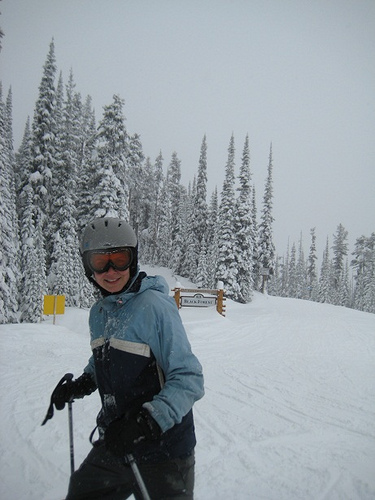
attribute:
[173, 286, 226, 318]
sign — in the background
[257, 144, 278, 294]
pine tree — snow covered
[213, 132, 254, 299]
pine tree — snow covered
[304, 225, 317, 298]
pine tree — snow covered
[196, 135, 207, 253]
pine tree — snow covered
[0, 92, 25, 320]
pine tree — snow covered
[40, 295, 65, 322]
sign — yellow 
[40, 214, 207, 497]
female skier — in blue, in black, dressed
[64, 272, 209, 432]
jacket — blue , black 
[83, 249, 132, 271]
goggles — orange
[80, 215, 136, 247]
helmet — grey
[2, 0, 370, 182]
sky — gray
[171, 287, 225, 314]
sign — big white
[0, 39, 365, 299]
pine trees — snow covered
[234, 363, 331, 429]
tracks — ski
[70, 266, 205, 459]
winter jacket — light blue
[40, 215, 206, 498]
person — in the foreground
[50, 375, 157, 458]
gloves — black 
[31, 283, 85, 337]
sign — yellow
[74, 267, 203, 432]
jacket — blue, white, black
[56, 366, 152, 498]
ski poles — silver